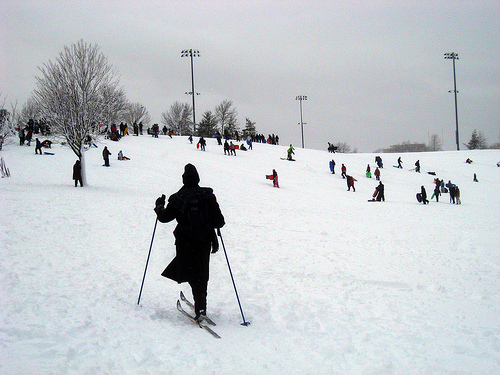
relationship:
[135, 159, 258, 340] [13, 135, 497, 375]
person on slope of hill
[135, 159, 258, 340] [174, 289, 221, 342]
person wearing skis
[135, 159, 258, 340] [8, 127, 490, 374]
person skiing over snow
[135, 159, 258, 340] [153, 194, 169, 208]
person has hand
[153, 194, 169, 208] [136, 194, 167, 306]
hand holding ski pole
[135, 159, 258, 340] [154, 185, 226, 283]
person wearing coat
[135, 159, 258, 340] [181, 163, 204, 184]
person has head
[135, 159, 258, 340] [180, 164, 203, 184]
person wearing cap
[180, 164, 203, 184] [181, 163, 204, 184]
cap covering head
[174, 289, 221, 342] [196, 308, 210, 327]
skis are attached to feet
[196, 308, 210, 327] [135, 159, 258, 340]
feet belong to person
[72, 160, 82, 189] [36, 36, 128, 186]
person leaning against tree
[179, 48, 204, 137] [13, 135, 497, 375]
lamp post mounted on top of hill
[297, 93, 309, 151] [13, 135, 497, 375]
lamp post mounted on top of hill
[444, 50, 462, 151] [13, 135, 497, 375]
lamp post mounted on top of hill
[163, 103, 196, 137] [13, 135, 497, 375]
tree on top of hill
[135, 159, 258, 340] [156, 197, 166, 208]
person wearing glove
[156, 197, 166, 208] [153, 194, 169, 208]
glove being worn on hand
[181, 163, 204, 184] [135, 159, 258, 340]
head of a person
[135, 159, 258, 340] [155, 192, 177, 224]
person has arm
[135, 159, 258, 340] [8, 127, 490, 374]
person on top of snow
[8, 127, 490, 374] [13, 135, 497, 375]
snow on surface of hill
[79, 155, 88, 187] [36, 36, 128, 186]
trunk at base of tree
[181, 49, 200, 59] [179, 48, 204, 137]
lights on top of lamp post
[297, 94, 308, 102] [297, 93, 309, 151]
lights on top of lamp post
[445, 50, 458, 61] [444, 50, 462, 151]
lights on top of lamp post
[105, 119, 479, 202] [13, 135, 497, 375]
people are scattered on hill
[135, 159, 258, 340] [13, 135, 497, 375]
person on hill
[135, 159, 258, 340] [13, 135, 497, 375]
person on surface of hill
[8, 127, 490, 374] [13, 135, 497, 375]
snow on hill